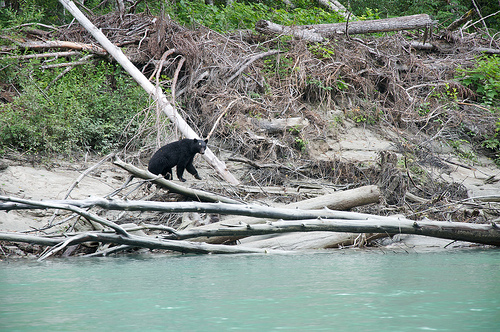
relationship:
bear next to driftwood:
[142, 138, 208, 191] [196, 46, 249, 113]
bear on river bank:
[142, 138, 208, 191] [107, 205, 333, 241]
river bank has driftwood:
[107, 205, 333, 241] [196, 46, 249, 113]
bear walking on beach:
[142, 138, 208, 191] [33, 171, 93, 198]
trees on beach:
[134, 24, 198, 54] [33, 171, 93, 198]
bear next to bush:
[142, 138, 208, 191] [195, 8, 238, 24]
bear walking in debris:
[142, 138, 208, 191] [235, 28, 405, 99]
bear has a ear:
[142, 138, 208, 191] [192, 137, 197, 144]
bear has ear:
[175, 145, 186, 161] [192, 137, 197, 144]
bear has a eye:
[175, 145, 186, 161] [202, 142, 205, 147]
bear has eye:
[175, 145, 186, 161] [202, 142, 205, 147]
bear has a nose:
[175, 145, 186, 161] [202, 148, 205, 153]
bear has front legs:
[175, 145, 186, 161] [173, 163, 202, 183]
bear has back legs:
[175, 145, 186, 161] [149, 163, 162, 178]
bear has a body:
[175, 145, 186, 161] [164, 150, 177, 163]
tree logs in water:
[129, 199, 259, 254] [183, 269, 389, 331]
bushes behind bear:
[27, 91, 123, 127] [175, 145, 186, 161]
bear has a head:
[175, 145, 186, 161] [194, 136, 209, 155]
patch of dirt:
[336, 133, 381, 160] [39, 171, 72, 193]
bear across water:
[142, 138, 208, 191] [183, 269, 389, 331]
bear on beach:
[142, 138, 208, 191] [33, 171, 93, 198]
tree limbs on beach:
[311, 161, 362, 192] [33, 171, 93, 198]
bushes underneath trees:
[27, 91, 123, 127] [134, 24, 198, 54]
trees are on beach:
[134, 24, 198, 54] [33, 171, 93, 198]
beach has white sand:
[33, 171, 93, 198] [6, 215, 31, 228]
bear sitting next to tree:
[175, 145, 186, 161] [91, 105, 135, 124]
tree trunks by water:
[116, 152, 148, 213] [183, 269, 389, 331]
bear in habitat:
[142, 138, 208, 191] [55, 55, 432, 249]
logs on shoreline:
[221, 198, 317, 220] [69, 214, 196, 257]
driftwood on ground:
[196, 46, 249, 113] [29, 220, 97, 247]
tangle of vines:
[142, 46, 214, 65] [296, 16, 354, 55]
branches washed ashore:
[169, 40, 244, 81] [332, 122, 418, 136]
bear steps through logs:
[175, 145, 186, 161] [221, 198, 317, 220]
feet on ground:
[179, 177, 204, 180] [29, 220, 97, 247]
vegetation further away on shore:
[187, 6, 251, 24] [45, 188, 114, 223]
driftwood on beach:
[196, 46, 249, 113] [33, 171, 93, 198]